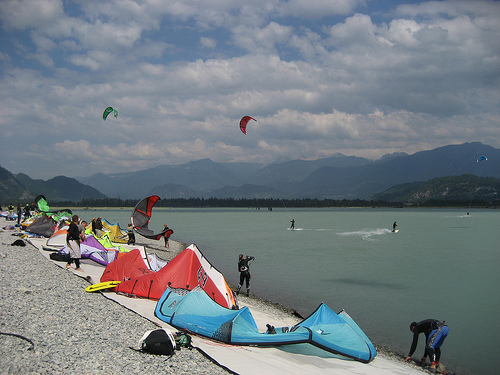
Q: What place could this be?
A: It is a beach.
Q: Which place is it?
A: It is a beach.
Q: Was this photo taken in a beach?
A: Yes, it was taken in a beach.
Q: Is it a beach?
A: Yes, it is a beach.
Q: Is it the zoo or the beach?
A: It is the beach.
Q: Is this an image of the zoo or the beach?
A: It is showing the beach.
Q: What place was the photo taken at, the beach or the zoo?
A: It was taken at the beach.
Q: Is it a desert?
A: No, it is a beach.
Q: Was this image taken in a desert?
A: No, the picture was taken in a beach.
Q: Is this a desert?
A: No, it is a beach.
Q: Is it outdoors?
A: Yes, it is outdoors.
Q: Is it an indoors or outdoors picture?
A: It is outdoors.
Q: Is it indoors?
A: No, it is outdoors.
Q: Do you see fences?
A: No, there are no fences.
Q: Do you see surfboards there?
A: Yes, there is a surfboard.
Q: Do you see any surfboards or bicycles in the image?
A: Yes, there is a surfboard.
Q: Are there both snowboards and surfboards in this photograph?
A: No, there is a surfboard but no snowboards.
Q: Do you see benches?
A: No, there are no benches.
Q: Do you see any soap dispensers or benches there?
A: No, there are no benches or soap dispensers.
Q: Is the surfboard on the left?
A: Yes, the surfboard is on the left of the image.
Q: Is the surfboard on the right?
A: No, the surfboard is on the left of the image.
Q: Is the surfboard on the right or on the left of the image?
A: The surfboard is on the left of the image.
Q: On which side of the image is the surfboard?
A: The surfboard is on the left of the image.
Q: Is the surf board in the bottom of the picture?
A: Yes, the surf board is in the bottom of the image.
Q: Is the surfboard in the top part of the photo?
A: No, the surfboard is in the bottom of the image.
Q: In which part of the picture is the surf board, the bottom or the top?
A: The surf board is in the bottom of the image.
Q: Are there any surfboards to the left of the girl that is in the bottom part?
A: Yes, there is a surfboard to the left of the girl.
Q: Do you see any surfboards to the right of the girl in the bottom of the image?
A: No, the surfboard is to the left of the girl.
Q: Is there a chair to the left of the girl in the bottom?
A: No, there is a surfboard to the left of the girl.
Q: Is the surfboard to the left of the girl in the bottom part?
A: Yes, the surfboard is to the left of the girl.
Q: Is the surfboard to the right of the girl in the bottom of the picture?
A: No, the surfboard is to the left of the girl.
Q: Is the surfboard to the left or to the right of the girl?
A: The surfboard is to the left of the girl.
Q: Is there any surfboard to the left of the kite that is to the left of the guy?
A: Yes, there is a surfboard to the left of the kite.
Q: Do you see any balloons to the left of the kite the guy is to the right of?
A: No, there is a surfboard to the left of the kite.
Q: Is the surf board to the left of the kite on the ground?
A: Yes, the surf board is to the left of the kite.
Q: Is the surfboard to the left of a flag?
A: No, the surfboard is to the left of the kite.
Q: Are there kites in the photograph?
A: Yes, there is a kite.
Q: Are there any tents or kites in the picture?
A: Yes, there is a kite.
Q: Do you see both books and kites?
A: No, there is a kite but no books.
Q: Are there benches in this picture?
A: No, there are no benches.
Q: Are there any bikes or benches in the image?
A: No, there are no benches or bikes.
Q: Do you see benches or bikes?
A: No, there are no benches or bikes.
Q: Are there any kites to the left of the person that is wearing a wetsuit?
A: Yes, there is a kite to the left of the person.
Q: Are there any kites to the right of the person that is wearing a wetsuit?
A: No, the kite is to the left of the person.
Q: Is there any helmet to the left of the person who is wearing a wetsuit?
A: No, there is a kite to the left of the person.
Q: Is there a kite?
A: Yes, there is a kite.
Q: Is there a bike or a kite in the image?
A: Yes, there is a kite.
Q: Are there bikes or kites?
A: Yes, there is a kite.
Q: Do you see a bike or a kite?
A: Yes, there is a kite.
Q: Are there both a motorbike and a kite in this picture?
A: No, there is a kite but no motorcycles.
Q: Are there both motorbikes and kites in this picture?
A: No, there is a kite but no motorcycles.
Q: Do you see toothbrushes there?
A: No, there are no toothbrushes.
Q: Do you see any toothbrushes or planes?
A: No, there are no toothbrushes or planes.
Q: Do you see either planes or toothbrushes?
A: No, there are no toothbrushes or planes.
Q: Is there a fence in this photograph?
A: No, there are no fences.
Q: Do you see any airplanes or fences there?
A: No, there are no fences or airplanes.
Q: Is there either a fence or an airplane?
A: No, there are no fences or airplanes.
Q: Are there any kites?
A: Yes, there is a kite.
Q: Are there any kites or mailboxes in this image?
A: Yes, there is a kite.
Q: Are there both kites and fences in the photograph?
A: No, there is a kite but no fences.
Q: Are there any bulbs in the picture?
A: No, there are no bulbs.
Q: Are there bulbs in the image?
A: No, there are no bulbs.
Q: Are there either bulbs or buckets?
A: No, there are no bulbs or buckets.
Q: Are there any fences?
A: No, there are no fences.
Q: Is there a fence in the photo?
A: No, there are no fences.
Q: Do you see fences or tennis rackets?
A: No, there are no fences or tennis rackets.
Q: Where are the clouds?
A: The clouds are in the sky.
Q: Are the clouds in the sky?
A: Yes, the clouds are in the sky.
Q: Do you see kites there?
A: Yes, there is a kite.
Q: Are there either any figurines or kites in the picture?
A: Yes, there is a kite.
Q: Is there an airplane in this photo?
A: No, there are no airplanes.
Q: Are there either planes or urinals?
A: No, there are no planes or urinals.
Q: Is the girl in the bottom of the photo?
A: Yes, the girl is in the bottom of the image.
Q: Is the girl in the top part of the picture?
A: No, the girl is in the bottom of the image.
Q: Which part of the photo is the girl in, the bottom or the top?
A: The girl is in the bottom of the image.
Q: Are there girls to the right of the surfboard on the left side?
A: Yes, there is a girl to the right of the surfboard.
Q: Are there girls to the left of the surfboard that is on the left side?
A: No, the girl is to the right of the surfboard.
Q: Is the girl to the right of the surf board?
A: Yes, the girl is to the right of the surf board.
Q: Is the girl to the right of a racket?
A: No, the girl is to the right of the surf board.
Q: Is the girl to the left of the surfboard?
A: No, the girl is to the right of the surfboard.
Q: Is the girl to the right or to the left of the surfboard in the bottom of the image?
A: The girl is to the right of the surfboard.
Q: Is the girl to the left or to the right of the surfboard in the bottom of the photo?
A: The girl is to the right of the surfboard.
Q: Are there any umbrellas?
A: No, there are no umbrellas.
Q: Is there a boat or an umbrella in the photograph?
A: No, there are no umbrellas or boats.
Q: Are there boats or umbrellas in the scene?
A: No, there are no umbrellas or boats.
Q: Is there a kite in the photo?
A: Yes, there is a kite.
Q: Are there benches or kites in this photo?
A: Yes, there is a kite.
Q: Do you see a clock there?
A: No, there are no clocks.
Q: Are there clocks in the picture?
A: No, there are no clocks.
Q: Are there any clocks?
A: No, there are no clocks.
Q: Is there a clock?
A: No, there are no clocks.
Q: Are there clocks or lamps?
A: No, there are no clocks or lamps.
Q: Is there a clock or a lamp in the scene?
A: No, there are no clocks or lamps.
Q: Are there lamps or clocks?
A: No, there are no clocks or lamps.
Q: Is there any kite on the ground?
A: Yes, there is a kite on the ground.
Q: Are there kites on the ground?
A: Yes, there is a kite on the ground.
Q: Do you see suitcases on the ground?
A: No, there is a kite on the ground.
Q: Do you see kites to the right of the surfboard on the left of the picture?
A: Yes, there is a kite to the right of the surf board.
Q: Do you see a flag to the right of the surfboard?
A: No, there is a kite to the right of the surfboard.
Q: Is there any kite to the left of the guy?
A: Yes, there is a kite to the left of the guy.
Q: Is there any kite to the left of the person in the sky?
A: Yes, there is a kite to the left of the guy.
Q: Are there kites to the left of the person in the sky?
A: Yes, there is a kite to the left of the guy.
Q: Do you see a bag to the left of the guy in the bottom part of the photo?
A: No, there is a kite to the left of the guy.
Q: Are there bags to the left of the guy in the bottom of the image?
A: No, there is a kite to the left of the guy.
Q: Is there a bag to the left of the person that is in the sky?
A: No, there is a kite to the left of the guy.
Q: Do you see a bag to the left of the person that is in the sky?
A: No, there is a kite to the left of the guy.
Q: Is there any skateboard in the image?
A: No, there are no skateboards.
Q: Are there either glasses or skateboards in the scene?
A: No, there are no skateboards or glasses.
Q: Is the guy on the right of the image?
A: Yes, the guy is on the right of the image.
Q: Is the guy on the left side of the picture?
A: No, the guy is on the right of the image.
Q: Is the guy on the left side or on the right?
A: The guy is on the right of the image.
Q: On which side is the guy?
A: The guy is on the right of the image.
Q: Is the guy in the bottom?
A: Yes, the guy is in the bottom of the image.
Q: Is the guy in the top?
A: No, the guy is in the bottom of the image.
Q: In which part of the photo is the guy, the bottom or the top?
A: The guy is in the bottom of the image.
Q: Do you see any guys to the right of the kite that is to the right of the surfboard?
A: Yes, there is a guy to the right of the kite.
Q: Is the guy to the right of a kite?
A: Yes, the guy is to the right of a kite.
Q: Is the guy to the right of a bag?
A: No, the guy is to the right of a kite.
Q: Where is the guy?
A: The guy is in the sky.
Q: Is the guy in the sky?
A: Yes, the guy is in the sky.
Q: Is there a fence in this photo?
A: No, there are no fences.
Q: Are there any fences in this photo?
A: No, there are no fences.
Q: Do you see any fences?
A: No, there are no fences.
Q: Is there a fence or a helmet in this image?
A: No, there are no fences or helmets.